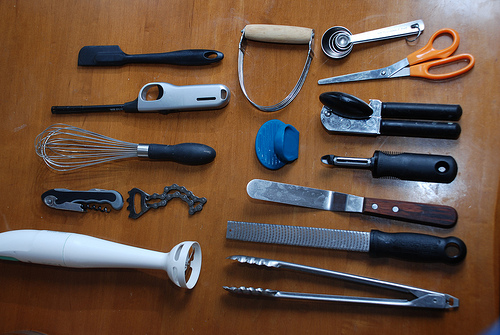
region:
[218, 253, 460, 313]
metal tongs for picking up food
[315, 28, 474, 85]
scissors with an orange handle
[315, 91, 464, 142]
manually operated can opener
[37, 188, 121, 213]
swiss army knife with corkscrew attached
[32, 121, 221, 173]
metal whisk with black handle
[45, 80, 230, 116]
long neck utility lighter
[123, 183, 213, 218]
small black bottle opener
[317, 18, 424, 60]
metal stacking measuring spoons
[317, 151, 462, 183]
black handled vegetable peeler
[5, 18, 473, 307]
tools that would commonly be found in a kitchen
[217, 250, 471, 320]
A pair of silver tongs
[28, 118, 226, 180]
A whisk with a black handle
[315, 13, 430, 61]
A set of silver measuring spoons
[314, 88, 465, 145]
A can opener with a black handle.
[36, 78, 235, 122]
A large lighter with a silver handle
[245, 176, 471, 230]
Small utensil used in baking.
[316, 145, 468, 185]
A peeler with a round black handle.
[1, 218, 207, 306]
A white utensil used in the kitchen.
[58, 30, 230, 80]
A small plastic spatula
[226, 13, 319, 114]
A masher with a wooden handle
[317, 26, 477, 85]
A pair of scissors on the table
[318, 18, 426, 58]
Measuring spoons on the table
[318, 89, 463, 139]
Can opener on the table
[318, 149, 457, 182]
peeling knife on the table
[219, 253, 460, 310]
Tongs on the table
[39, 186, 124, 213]
Bottle opener on the table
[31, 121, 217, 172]
Eggbeater on the table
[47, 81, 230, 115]
Lighter on the table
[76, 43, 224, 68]
Brush on the table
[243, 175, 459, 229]
Server on the table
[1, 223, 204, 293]
white hand mixer on table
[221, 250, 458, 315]
silver tongs on table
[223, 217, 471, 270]
black handled zester with silver blade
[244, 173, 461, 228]
frosting smoother with wood handle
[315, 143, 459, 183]
vegetable peeler with black handle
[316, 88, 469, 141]
hand held can opener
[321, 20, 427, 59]
measuring spoons on ring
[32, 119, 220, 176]
whisk with black handle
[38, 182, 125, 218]
folding cork screw on table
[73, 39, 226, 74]
black bowl scraper on table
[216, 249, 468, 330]
metal tongs on a table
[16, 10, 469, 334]
kitchen utensils on a table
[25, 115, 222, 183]
whisk on a table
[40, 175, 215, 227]
can openers on a table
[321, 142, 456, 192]
peeler on a table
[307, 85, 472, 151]
can opener on a table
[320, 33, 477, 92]
scissors on a table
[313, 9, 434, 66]
measuring spoons on a table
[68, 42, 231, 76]
spatula on a table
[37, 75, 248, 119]
lighter on a table